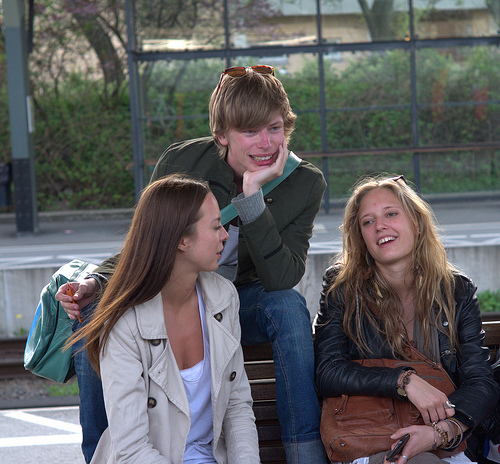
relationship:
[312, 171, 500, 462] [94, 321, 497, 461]
girl sitting on bench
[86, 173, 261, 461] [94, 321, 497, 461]
girl sitting on bench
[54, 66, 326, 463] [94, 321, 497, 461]
boy sitting on bench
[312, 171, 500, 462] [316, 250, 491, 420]
girl wearing jacket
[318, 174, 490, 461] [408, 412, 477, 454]
girl has wrist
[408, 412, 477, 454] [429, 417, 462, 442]
wrist has bracelet's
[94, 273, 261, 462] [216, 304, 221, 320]
pea-coat with button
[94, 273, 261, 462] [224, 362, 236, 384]
pea-coat with button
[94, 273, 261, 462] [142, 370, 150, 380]
pea-coat with button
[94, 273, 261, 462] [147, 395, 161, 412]
pea-coat with button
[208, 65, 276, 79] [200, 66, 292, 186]
sunglasses on top of head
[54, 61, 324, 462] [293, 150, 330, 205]
boy has shoulder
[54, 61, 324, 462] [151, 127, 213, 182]
boy has shoulder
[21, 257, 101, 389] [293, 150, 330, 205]
bag over shoulder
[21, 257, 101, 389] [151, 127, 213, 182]
bag over shoulder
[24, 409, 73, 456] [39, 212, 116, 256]
lines painted on street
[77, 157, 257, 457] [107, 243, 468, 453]
girl on bench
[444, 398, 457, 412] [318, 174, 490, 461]
silver ring on girl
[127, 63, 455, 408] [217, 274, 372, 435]
leg on jeans